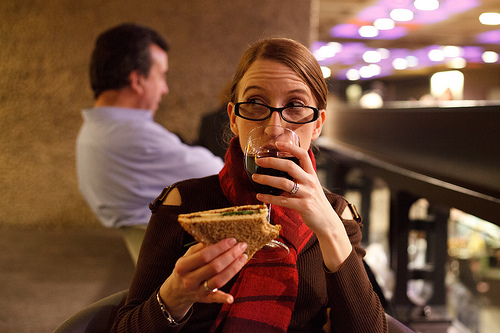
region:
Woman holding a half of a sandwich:
[124, 34, 389, 331]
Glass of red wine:
[243, 124, 299, 262]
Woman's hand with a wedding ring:
[251, 142, 338, 239]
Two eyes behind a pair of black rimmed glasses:
[228, 93, 321, 125]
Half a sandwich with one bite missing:
[176, 202, 281, 266]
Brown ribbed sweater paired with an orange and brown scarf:
[116, 135, 388, 332]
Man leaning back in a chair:
[73, 19, 225, 264]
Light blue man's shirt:
[74, 103, 224, 228]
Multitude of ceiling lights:
[314, 1, 499, 78]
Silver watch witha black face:
[153, 289, 180, 327]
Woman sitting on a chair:
[111, 37, 388, 331]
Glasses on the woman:
[230, 97, 321, 124]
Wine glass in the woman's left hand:
[242, 123, 298, 259]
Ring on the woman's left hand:
[287, 180, 298, 193]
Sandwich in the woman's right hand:
[176, 204, 283, 263]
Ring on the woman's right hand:
[202, 279, 217, 294]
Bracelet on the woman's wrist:
[153, 292, 182, 330]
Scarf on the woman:
[216, 133, 318, 332]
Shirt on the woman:
[108, 173, 385, 332]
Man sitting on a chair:
[74, 18, 224, 228]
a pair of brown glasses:
[215, 90, 331, 126]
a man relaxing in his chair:
[66, 12, 230, 243]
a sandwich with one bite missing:
[169, 195, 308, 263]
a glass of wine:
[231, 110, 308, 257]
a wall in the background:
[11, 15, 76, 286]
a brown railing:
[331, 140, 493, 321]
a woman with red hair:
[201, 19, 335, 219]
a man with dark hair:
[72, 10, 183, 135]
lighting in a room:
[311, 3, 499, 120]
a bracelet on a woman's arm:
[133, 279, 211, 331]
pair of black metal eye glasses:
[229, 88, 329, 129]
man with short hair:
[69, 18, 181, 119]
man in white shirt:
[59, 19, 213, 223]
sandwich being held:
[159, 194, 292, 272]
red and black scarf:
[244, 259, 297, 331]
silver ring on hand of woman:
[283, 180, 306, 201]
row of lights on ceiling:
[355, 0, 452, 49]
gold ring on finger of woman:
[201, 274, 224, 301]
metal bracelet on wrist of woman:
[149, 285, 187, 330]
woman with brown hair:
[182, 25, 364, 212]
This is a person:
[78, 5, 225, 265]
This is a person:
[197, 22, 363, 328]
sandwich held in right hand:
[166, 202, 283, 282]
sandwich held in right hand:
[170, 188, 287, 286]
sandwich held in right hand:
[166, 193, 291, 268]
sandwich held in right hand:
[169, 200, 300, 267]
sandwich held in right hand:
[164, 195, 291, 262]